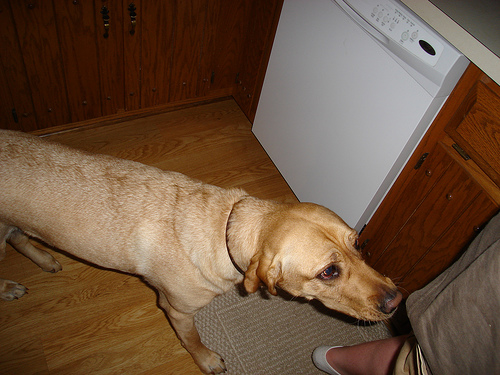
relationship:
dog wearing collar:
[0, 129, 403, 373] [225, 192, 251, 275]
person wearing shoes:
[311, 182, 499, 375] [259, 326, 361, 373]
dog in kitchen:
[3, 129, 379, 352] [5, 7, 495, 373]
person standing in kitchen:
[311, 182, 499, 375] [5, 7, 495, 373]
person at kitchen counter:
[311, 182, 498, 373] [394, 1, 498, 82]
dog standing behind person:
[0, 129, 403, 373] [311, 182, 499, 375]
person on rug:
[311, 182, 499, 375] [183, 284, 399, 374]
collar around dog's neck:
[224, 192, 245, 273] [229, 186, 272, 290]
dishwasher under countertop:
[247, 0, 471, 239] [399, 0, 499, 90]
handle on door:
[100, 5, 110, 37] [2, 1, 119, 131]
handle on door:
[126, 2, 138, 35] [121, 0, 216, 110]